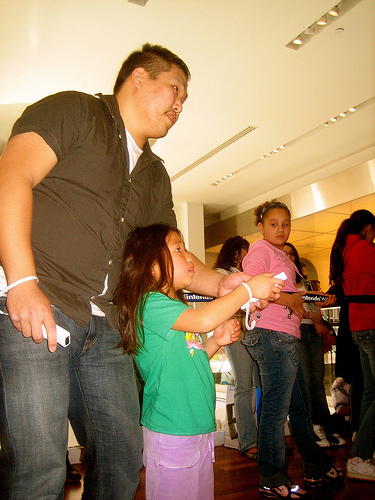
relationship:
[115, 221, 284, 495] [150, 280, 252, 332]
person has arm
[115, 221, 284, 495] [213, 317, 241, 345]
person has hand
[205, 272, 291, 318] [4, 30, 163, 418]
hand part of person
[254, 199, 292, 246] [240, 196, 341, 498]
head of person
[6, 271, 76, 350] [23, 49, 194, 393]
hand of person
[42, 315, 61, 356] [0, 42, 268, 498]
finger of man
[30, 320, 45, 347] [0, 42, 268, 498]
finger of man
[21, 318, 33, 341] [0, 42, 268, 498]
finger of man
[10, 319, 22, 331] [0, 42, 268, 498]
finger of man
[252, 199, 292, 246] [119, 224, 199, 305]
head of person head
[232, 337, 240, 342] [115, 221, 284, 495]
finger of a person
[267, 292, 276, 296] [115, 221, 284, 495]
finger of a person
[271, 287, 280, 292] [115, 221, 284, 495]
finger of a person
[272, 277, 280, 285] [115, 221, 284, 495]
finger of a person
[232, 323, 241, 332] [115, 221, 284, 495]
finger of a person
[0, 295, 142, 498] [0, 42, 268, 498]
pants on man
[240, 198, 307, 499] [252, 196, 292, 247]
person has head